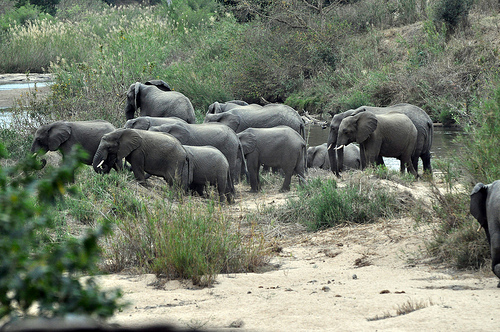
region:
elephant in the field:
[350, 108, 410, 158]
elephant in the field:
[390, 100, 413, 109]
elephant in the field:
[237, 133, 293, 160]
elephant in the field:
[242, 98, 294, 124]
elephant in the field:
[188, 158, 212, 189]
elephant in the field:
[48, 127, 93, 152]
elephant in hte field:
[128, 77, 185, 112]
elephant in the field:
[210, 96, 235, 111]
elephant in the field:
[126, 112, 174, 130]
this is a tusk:
[94, 145, 134, 191]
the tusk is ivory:
[90, 148, 138, 223]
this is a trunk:
[297, 115, 367, 216]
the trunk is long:
[311, 128, 386, 222]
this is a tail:
[380, 151, 422, 183]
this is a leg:
[240, 188, 288, 256]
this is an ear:
[109, 107, 146, 146]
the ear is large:
[350, 125, 371, 160]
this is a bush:
[223, 229, 260, 284]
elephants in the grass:
[33, 70, 483, 234]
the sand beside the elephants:
[134, 230, 497, 327]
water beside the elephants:
[431, 133, 476, 169]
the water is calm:
[434, 126, 474, 168]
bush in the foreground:
[1, 142, 127, 325]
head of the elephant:
[76, 123, 136, 183]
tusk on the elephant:
[331, 140, 346, 153]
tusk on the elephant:
[91, 154, 106, 168]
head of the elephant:
[331, 104, 375, 171]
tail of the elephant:
[230, 134, 257, 173]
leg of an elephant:
[216, 176, 246, 212]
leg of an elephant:
[239, 165, 256, 205]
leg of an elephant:
[270, 156, 291, 188]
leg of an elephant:
[356, 146, 374, 175]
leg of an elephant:
[392, 159, 419, 178]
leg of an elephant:
[408, 133, 435, 171]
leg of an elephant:
[173, 178, 200, 210]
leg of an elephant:
[123, 170, 154, 197]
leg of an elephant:
[483, 233, 499, 281]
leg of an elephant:
[264, 161, 279, 181]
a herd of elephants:
[26, 75, 436, 184]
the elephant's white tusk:
[94, 159, 108, 169]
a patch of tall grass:
[106, 190, 286, 288]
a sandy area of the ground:
[20, 180, 498, 330]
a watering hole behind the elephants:
[298, 112, 498, 175]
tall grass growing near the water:
[1, 6, 158, 71]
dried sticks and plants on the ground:
[242, 203, 304, 244]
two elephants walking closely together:
[321, 99, 435, 180]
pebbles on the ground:
[257, 272, 362, 292]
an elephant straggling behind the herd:
[466, 169, 499, 288]